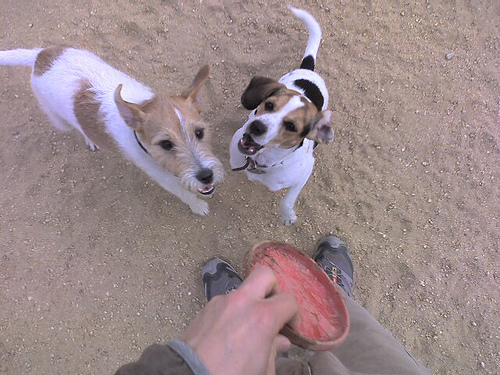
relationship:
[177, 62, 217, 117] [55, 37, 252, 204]
ear on dog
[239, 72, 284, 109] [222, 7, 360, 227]
ear on dog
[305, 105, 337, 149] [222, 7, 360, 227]
ear on dog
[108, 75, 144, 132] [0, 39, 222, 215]
ear on dog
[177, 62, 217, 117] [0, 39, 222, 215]
ear on dog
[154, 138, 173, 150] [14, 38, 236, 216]
eye on dog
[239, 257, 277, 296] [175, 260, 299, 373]
finger on hand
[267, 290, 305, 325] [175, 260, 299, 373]
finger on hand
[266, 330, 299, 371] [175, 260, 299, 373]
finger on hand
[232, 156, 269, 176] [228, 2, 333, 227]
collar on dog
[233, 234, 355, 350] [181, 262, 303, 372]
disc in hand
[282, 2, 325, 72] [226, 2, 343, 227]
tail of dog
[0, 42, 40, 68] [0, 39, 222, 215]
tail of dog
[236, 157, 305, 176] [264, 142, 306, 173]
collar on neck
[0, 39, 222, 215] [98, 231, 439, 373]
dog looking at man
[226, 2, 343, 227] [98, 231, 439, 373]
dog looking at man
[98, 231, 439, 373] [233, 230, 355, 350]
man holding disc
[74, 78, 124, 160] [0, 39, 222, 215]
spot on dog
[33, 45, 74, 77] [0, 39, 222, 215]
spot on dog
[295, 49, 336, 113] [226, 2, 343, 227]
spots on dog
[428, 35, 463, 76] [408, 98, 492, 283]
pebbles in dirt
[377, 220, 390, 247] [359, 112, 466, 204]
pebbles in dirt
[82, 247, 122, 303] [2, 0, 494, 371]
pebbles in dirt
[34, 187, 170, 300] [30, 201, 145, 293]
pebbles in dirt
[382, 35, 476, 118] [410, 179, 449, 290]
pebbles in dirt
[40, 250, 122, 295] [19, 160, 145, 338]
pebbles in dirt